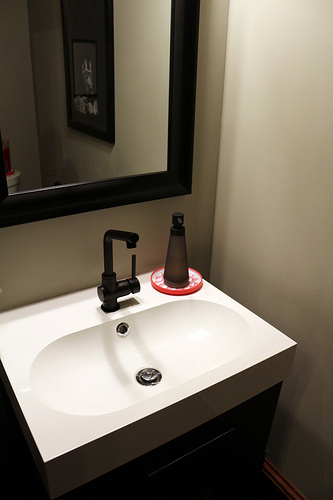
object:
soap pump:
[160, 214, 192, 287]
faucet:
[96, 227, 141, 314]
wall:
[276, 78, 290, 103]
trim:
[261, 456, 308, 498]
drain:
[136, 367, 162, 387]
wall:
[1, 2, 332, 499]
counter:
[1, 271, 297, 465]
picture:
[60, 1, 116, 144]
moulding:
[262, 452, 309, 499]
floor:
[134, 454, 298, 498]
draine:
[135, 366, 162, 386]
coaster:
[150, 266, 202, 295]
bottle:
[163, 211, 189, 287]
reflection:
[66, 31, 128, 127]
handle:
[130, 254, 139, 288]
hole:
[135, 367, 162, 388]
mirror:
[0, 10, 200, 224]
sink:
[25, 297, 295, 425]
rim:
[98, 173, 192, 208]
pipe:
[96, 238, 117, 318]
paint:
[16, 236, 95, 286]